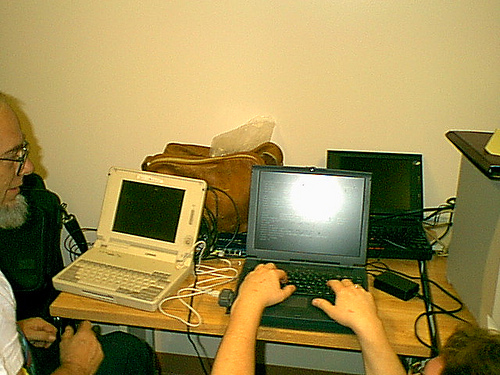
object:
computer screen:
[246, 164, 372, 265]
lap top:
[226, 163, 373, 334]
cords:
[158, 185, 248, 374]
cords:
[64, 226, 98, 261]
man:
[0, 91, 160, 375]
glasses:
[1, 139, 30, 177]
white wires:
[158, 240, 239, 328]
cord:
[363, 196, 472, 354]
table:
[49, 182, 496, 358]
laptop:
[50, 165, 208, 310]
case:
[140, 115, 284, 234]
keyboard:
[58, 257, 173, 303]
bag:
[0, 187, 64, 299]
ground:
[157, 348, 365, 374]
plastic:
[208, 114, 275, 157]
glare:
[256, 170, 364, 257]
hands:
[237, 261, 296, 307]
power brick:
[372, 270, 419, 302]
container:
[445, 128, 499, 322]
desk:
[48, 220, 479, 358]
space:
[371, 253, 468, 353]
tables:
[46, 220, 480, 375]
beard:
[1, 193, 31, 231]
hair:
[0, 193, 31, 228]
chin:
[1, 195, 20, 216]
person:
[212, 263, 500, 375]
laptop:
[327, 150, 450, 261]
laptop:
[218, 164, 372, 335]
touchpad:
[282, 297, 308, 309]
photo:
[0, 0, 500, 375]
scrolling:
[370, 271, 464, 323]